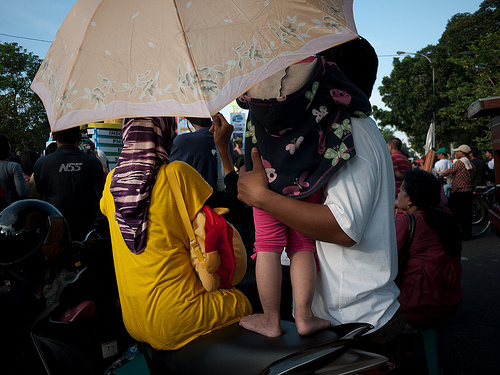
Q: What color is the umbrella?
A: Tan.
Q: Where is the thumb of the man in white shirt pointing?
A: Upward.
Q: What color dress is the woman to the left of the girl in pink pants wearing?
A: Yellow.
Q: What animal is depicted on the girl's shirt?
A: Butterflies.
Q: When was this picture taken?
A: Day time.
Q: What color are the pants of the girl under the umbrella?
A: Pink.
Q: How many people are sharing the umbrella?
A: Three.